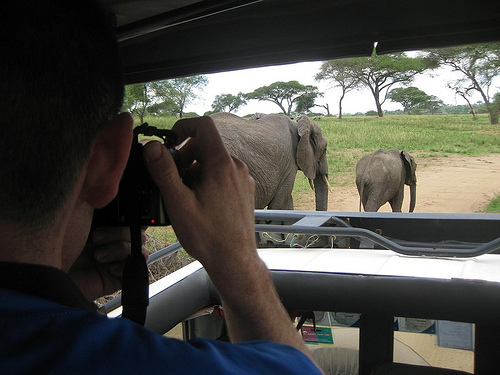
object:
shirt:
[0, 259, 329, 374]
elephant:
[352, 146, 418, 212]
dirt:
[290, 153, 498, 215]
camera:
[90, 120, 184, 229]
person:
[0, 0, 330, 375]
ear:
[84, 109, 136, 211]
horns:
[317, 172, 334, 196]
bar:
[250, 222, 498, 258]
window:
[123, 43, 500, 214]